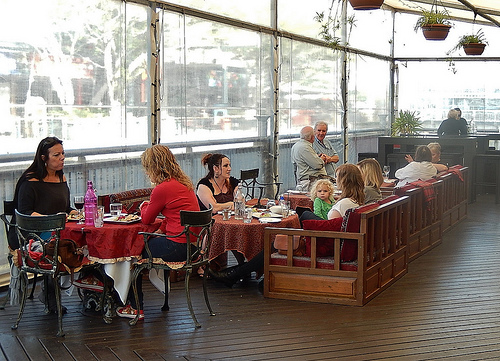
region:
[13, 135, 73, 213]
Diner in nice restaurant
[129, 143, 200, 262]
Diner in nice restaurant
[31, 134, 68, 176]
Head of hungry diner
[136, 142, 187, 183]
Head of hungry diner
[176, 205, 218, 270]
Brown back of restaurant chair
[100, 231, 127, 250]
Part of red table cover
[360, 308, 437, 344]
Part of brown wooden floor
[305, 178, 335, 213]
Blonde child in restaurant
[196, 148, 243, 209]
Hungry diner in restaurant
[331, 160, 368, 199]
Head of woman holding child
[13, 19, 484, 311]
this is a cafe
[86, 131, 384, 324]
these people are eating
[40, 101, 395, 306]
these people are drinking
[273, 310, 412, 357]
the floor here is wood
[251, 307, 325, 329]
the wood is dark brown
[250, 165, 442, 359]
the benchs are made of wood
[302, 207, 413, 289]
the pillows are red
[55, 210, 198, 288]
the table cloth is red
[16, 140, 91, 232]
the lady is wearing brown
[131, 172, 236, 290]
this lady is wearing red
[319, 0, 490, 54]
Three plants are hanging in pots.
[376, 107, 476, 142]
Two people facing each other at a table.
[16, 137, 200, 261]
Two women are sitting at a table.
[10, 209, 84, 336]
A purse is on a chair.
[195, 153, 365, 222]
Two women and a little gira are at a table.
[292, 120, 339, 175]
Two gray haired men are together.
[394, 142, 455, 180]
A man and a woman are seated side by side.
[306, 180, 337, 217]
A little girl has a green shirt.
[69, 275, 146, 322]
Two feet wearing red and white sneakers.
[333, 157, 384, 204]
Two heads, one has brown and one blonde hair.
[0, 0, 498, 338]
people in a restaurant-style setting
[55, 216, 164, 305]
red tablecloth over a white cloth on table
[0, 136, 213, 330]
two women seated across from each other at a table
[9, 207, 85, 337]
brown purse on a chair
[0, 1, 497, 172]
large windows on walls and ceiling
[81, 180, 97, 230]
a tall pink bottle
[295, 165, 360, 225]
little girl sitting with a woman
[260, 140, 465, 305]
people seated in low red cushioned seats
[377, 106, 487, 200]
two people behind a tall dark counter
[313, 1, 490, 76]
green plants in planters hung from ceiling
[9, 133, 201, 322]
Two women having a meal together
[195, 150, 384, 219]
Three women and a child having a meal together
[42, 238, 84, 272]
Burgundy purse on a chair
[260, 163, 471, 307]
Three wood framed sofas in a row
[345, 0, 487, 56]
Three terra cotta pots hanging from a ceiling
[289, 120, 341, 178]
Two older men talking together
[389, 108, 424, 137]
Small plant on a ledge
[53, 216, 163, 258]
Bright red tablecloth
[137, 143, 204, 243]
Woman wearing a bright red shirt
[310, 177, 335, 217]
Young blonde girl wearing a green shirt